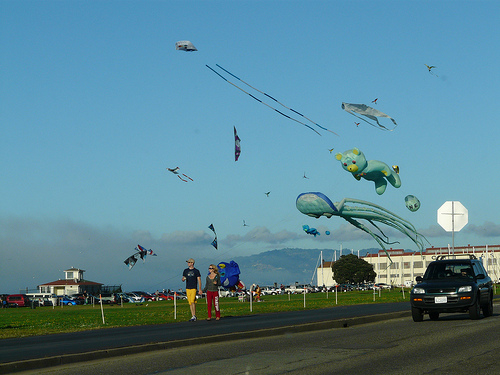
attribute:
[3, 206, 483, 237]
clouds — white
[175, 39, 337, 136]
kite — large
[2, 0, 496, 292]
sky — blue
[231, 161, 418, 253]
kite — large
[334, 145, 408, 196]
kite — large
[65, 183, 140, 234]
clouds — white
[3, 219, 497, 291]
clouds — white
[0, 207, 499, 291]
clouds — white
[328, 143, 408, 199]
kite — large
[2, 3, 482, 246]
sky — blue